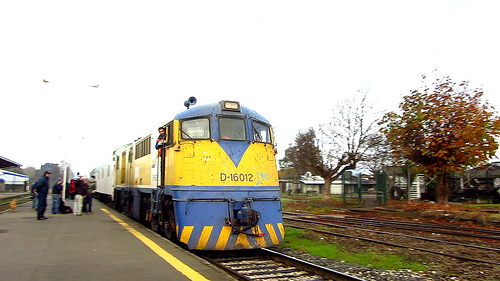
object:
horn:
[184, 96, 197, 109]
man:
[154, 127, 166, 158]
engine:
[153, 97, 286, 251]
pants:
[51, 194, 61, 213]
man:
[86, 175, 97, 213]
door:
[121, 151, 127, 186]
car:
[90, 96, 286, 250]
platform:
[0, 193, 240, 281]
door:
[158, 126, 166, 187]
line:
[124, 227, 211, 281]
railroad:
[195, 247, 366, 281]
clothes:
[31, 176, 51, 214]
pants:
[36, 194, 47, 217]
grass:
[282, 226, 430, 270]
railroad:
[285, 217, 500, 266]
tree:
[316, 91, 390, 200]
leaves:
[278, 126, 329, 178]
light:
[220, 100, 241, 111]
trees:
[278, 126, 325, 180]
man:
[30, 171, 52, 220]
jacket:
[31, 175, 49, 194]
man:
[72, 175, 85, 215]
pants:
[73, 194, 83, 215]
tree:
[372, 73, 498, 204]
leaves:
[377, 76, 498, 170]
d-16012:
[220, 173, 253, 182]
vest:
[158, 135, 163, 153]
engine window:
[181, 117, 211, 139]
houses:
[277, 161, 500, 202]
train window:
[251, 119, 272, 144]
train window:
[220, 117, 247, 140]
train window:
[128, 147, 134, 164]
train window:
[133, 136, 152, 160]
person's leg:
[36, 199, 47, 217]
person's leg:
[52, 197, 60, 212]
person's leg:
[72, 196, 83, 214]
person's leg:
[88, 197, 93, 210]